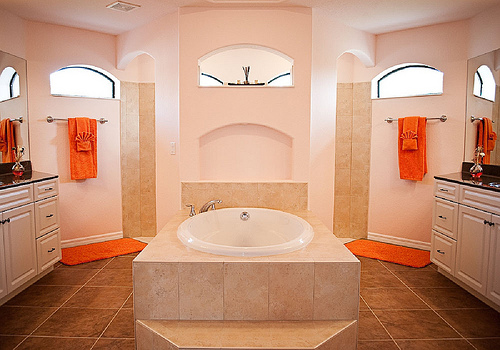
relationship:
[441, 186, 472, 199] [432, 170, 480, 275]
handle on vanity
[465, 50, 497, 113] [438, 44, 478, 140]
mirror on wall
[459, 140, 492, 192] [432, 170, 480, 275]
vase on vanity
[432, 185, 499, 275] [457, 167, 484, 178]
cabinets under sink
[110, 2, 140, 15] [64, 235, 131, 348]
vent above ground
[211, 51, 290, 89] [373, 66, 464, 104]
light streaming in window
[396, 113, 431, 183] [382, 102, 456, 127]
towels on rack